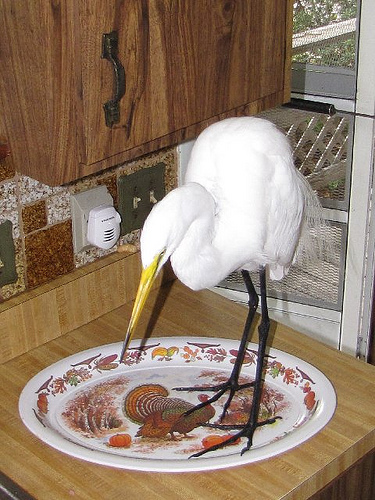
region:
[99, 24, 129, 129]
older brass cabinet handle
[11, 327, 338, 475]
ceramic white plate with Thanksgiving pattern on it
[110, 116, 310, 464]
crane standing on plate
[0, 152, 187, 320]
brown, black and white tile backsplash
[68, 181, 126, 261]
wall mounted plug extender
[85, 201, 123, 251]
white plug in room scenter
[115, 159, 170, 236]
two-switch black light panel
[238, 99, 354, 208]
lattice work on outside patio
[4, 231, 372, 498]
wood-style formica counter top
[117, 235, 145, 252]
pet treats on kitchen ledge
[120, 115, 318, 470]
A large white bird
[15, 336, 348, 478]
A fall themed platter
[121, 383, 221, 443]
A turkey design on a platter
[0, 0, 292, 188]
A wall-hung wooden cabinet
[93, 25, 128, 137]
A metal handle on a cabinet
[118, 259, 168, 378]
A bird's long yellow beak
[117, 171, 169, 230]
A two-switch light switch plate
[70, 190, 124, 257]
An outlet with a white device plugged in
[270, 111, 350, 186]
Wooden lattice outside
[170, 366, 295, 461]
Black bird feet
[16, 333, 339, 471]
paper plate with Thanksgiving theme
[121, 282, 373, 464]
wooden counter top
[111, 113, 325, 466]
white bird with long black legs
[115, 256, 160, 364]
long pointy yellow bill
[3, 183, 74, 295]
grainy earth tone tiles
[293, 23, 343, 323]
screen on exterior door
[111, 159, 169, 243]
grey plated wall switch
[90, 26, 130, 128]
black cabinet handle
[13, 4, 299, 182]
dark wood wall cabinet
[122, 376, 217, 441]
drawing of turkey on plate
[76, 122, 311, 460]
bird standing on a plate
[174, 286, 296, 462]
long and skinny black legs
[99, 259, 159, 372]
long yellow beak with a black tip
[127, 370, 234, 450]
drawing of a turkey on the plate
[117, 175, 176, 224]
one light switch is up and the other is down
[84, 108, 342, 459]
large white bird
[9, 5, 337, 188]
wooden cabinet with a black cabinet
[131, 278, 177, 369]
shadow of the bird's beak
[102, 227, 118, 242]
four black lines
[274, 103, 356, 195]
white fence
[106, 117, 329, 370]
a white bird with a long beak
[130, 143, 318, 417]
a white bird with long legs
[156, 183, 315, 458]
a bird with long black legs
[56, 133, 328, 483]
a bird standing on a plate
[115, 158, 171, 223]
a double light switch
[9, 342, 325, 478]
a white plate with a picture on it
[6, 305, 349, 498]
a brown counter top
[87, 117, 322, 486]
a white bird on a counter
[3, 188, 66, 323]
a tile wall